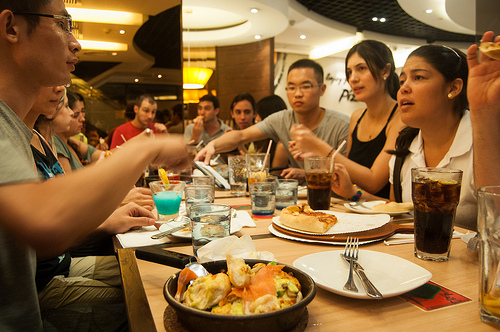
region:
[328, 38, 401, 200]
woman wearing black tank top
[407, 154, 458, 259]
clear glass with soda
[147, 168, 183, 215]
blue cocktail with lemon slice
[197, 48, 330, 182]
man reaching for bill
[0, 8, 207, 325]
the person is eating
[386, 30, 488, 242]
the person is eating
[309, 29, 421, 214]
the person is eating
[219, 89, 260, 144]
the person is eating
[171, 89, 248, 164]
the person is eating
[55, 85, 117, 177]
the person is eating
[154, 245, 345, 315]
a ray of food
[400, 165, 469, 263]
a glass of iced cola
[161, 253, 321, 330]
a dark clay pot of cabbage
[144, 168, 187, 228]
a cocktail that is teal in color with lemon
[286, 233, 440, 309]
a white plate with knife and fork on it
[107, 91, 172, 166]
a man wearing a red shirt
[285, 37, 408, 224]
a woman wearing a black sleeveless top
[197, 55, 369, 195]
a guy with a buzz cut wearing a grey shirt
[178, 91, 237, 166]
a guy biting into some food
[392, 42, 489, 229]
a girl wearing a white shirt and headband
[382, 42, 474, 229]
person sitting eating with other person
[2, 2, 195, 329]
person sitting eating with other person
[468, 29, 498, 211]
person sitting eating with other person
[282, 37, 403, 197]
person sitting eating with other person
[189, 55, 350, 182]
person sitting eating with other person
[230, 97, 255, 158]
person sitting eating with other person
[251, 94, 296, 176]
person sitting eating with other person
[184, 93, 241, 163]
person sitting eating with other person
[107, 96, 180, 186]
person sitting eating with other person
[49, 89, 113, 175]
person sitting eating with other person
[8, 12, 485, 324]
young people seated around long table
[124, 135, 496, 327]
glasses and plates on top of table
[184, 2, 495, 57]
black and white swirling design on ceiling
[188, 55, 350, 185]
young man reaching across table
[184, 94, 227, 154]
man bringing food to his mouth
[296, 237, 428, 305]
fork crossed over knife on white plate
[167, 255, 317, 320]
shallow dish with dumplings and carrot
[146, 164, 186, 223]
turquoise drink with orange slice on rim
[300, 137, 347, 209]
glass of soda with straw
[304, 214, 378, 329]
knife and fork on plate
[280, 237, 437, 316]
white square plate on table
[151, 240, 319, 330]
dish of food on table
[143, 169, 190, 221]
blue drink in glass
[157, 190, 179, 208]
blue liquid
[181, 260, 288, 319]
food on the plate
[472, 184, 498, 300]
a clear glass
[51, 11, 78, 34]
man wearing glasses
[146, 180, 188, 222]
Short clear drinking glass with blue liquid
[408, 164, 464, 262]
Tall glass with cola and ice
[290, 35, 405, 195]
Womann in tank top with dark brown hair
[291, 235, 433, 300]
Empty white plate with a knife and fork on it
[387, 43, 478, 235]
Woman with long hair wearing a white collared shirt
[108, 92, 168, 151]
Man in red shirt with a receding hairline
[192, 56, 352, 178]
Asian man in a grey shirt reaching across the table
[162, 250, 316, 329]
Dark colored bowl with orange and yellow food in it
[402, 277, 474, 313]
Red and black postcard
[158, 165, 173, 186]
Slice of orange perched on the side of a drinking glass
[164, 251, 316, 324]
The black bowl of food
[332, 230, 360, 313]
The silver fork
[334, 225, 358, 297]
A silver fork